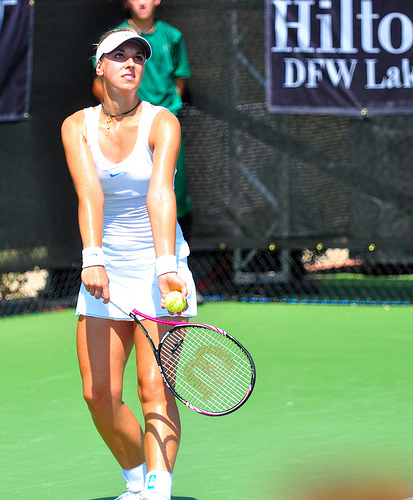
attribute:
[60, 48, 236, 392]
girl — playing, serving, white, sweating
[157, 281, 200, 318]
ball — green, yellow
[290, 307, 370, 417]
court — green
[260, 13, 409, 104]
sign — black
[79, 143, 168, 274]
outfit — white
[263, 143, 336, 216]
fence — close, black